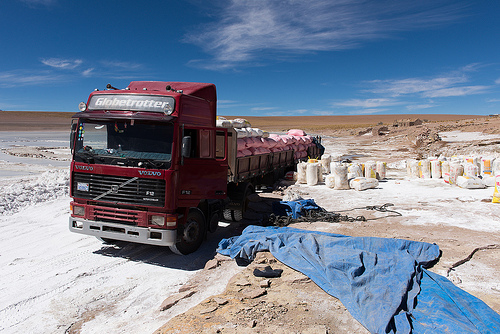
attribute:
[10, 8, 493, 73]
sky — pictured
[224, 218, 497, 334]
tent — pictured, partially visible, blue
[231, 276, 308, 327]
ground — pictured, rocky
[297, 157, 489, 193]
sacks — pictured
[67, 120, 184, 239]
truck — pictured, red, empty, volvo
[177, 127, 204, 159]
window — pictured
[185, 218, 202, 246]
rim — truck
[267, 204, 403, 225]
cord — black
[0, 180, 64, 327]
sand — white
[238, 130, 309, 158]
bags — pink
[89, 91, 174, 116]
logo — globetrotter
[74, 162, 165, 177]
volvo — silver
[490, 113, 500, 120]
house — brown